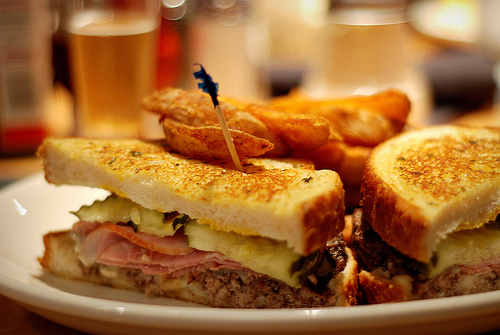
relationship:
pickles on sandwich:
[70, 192, 322, 288] [37, 136, 360, 309]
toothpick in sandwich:
[192, 60, 245, 170] [37, 136, 360, 309]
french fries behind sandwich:
[142, 88, 411, 240] [37, 136, 360, 309]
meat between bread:
[95, 220, 198, 255] [37, 135, 357, 306]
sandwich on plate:
[37, 136, 360, 309] [2, 170, 499, 333]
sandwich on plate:
[360, 124, 500, 304] [2, 170, 499, 333]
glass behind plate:
[65, 0, 160, 138] [2, 170, 499, 333]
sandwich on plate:
[27, 120, 357, 335] [5, 132, 498, 335]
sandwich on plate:
[27, 120, 357, 335] [7, 146, 491, 321]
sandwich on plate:
[37, 136, 360, 309] [5, 132, 498, 335]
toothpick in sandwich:
[192, 60, 247, 172] [27, 120, 357, 335]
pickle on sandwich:
[55, 185, 138, 221] [27, 120, 357, 335]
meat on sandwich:
[87, 206, 235, 287] [27, 120, 357, 335]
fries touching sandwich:
[134, 61, 414, 201] [27, 120, 357, 335]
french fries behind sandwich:
[142, 88, 292, 158] [27, 120, 357, 335]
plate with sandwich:
[5, 132, 498, 335] [27, 120, 357, 335]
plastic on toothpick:
[187, 59, 228, 99] [200, 110, 244, 177]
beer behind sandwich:
[70, 20, 157, 138] [27, 120, 357, 335]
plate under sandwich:
[5, 132, 498, 335] [27, 120, 357, 335]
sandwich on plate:
[38, 124, 498, 305] [2, 170, 499, 333]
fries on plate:
[139, 89, 412, 210] [2, 170, 499, 333]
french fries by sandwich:
[140, 85, 412, 214] [38, 124, 498, 305]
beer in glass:
[78, 51, 135, 99] [82, 99, 127, 152]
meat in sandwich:
[98, 220, 230, 278] [37, 136, 360, 309]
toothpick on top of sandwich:
[192, 60, 247, 172] [37, 136, 360, 309]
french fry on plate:
[140, 85, 290, 158] [2, 170, 499, 333]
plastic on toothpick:
[190, 63, 220, 108] [192, 60, 247, 172]